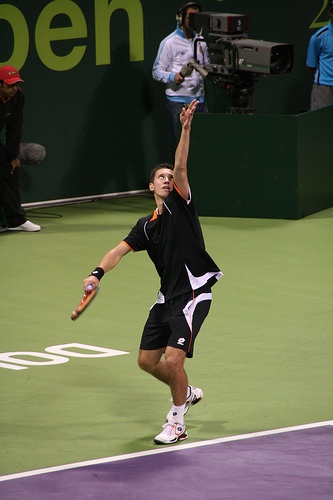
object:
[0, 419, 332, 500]
court portion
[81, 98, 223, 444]
man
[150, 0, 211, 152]
man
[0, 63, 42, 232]
man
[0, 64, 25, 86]
cap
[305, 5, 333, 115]
man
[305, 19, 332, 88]
shirt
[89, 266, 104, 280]
wristband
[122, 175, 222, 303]
shirt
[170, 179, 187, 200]
lines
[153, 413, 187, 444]
shoes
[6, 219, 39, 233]
shoes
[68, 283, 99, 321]
tennis racket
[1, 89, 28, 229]
black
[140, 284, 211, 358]
shorts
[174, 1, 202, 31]
headphones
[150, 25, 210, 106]
jacket